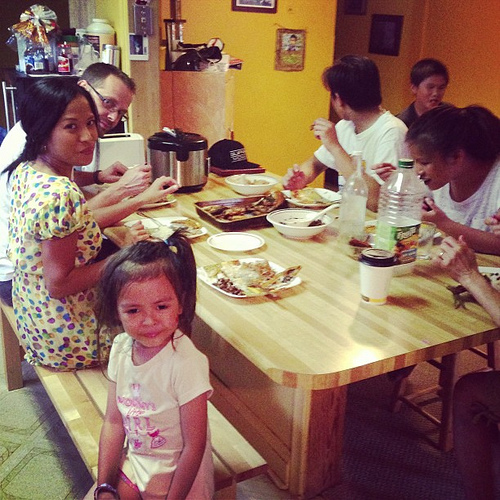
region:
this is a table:
[252, 298, 350, 391]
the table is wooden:
[263, 305, 353, 380]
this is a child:
[111, 228, 209, 496]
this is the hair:
[169, 231, 188, 274]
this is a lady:
[19, 77, 97, 230]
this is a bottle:
[379, 155, 419, 228]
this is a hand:
[174, 390, 208, 460]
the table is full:
[198, 155, 370, 324]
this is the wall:
[240, 74, 307, 128]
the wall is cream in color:
[237, 76, 284, 130]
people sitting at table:
[2, 53, 496, 497]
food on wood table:
[99, 159, 498, 389]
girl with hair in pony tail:
[90, 229, 210, 498]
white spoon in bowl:
[269, 201, 339, 238]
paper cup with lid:
[359, 249, 398, 305]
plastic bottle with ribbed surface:
[376, 157, 426, 276]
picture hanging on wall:
[274, 26, 311, 71]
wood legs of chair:
[390, 346, 495, 449]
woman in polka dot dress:
[8, 73, 110, 370]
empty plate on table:
[206, 231, 264, 252]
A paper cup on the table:
[360, 247, 396, 305]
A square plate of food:
[198, 258, 301, 298]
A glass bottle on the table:
[342, 150, 366, 248]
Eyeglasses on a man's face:
[83, 74, 128, 119]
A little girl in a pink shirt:
[92, 233, 217, 499]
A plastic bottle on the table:
[376, 156, 422, 273]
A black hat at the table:
[208, 139, 259, 168]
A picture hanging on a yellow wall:
[272, 28, 305, 73]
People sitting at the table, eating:
[274, 58, 498, 268]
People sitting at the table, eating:
[2, 62, 178, 352]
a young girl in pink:
[95, 230, 209, 499]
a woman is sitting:
[10, 87, 151, 363]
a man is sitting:
[3, 58, 156, 299]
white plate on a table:
[205, 232, 264, 249]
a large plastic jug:
[375, 156, 423, 275]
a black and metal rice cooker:
[146, 127, 212, 196]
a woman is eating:
[379, 104, 499, 244]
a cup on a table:
[359, 248, 396, 307]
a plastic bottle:
[338, 157, 368, 255]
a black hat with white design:
[206, 136, 260, 168]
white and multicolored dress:
[6, 161, 113, 373]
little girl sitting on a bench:
[82, 226, 213, 498]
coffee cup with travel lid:
[356, 247, 395, 304]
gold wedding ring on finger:
[438, 250, 443, 258]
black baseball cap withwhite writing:
[208, 138, 261, 168]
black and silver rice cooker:
[148, 125, 210, 191]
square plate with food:
[196, 255, 302, 297]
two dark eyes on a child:
[124, 303, 168, 314]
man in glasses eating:
[1, 62, 151, 305]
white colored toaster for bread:
[83, 133, 145, 172]